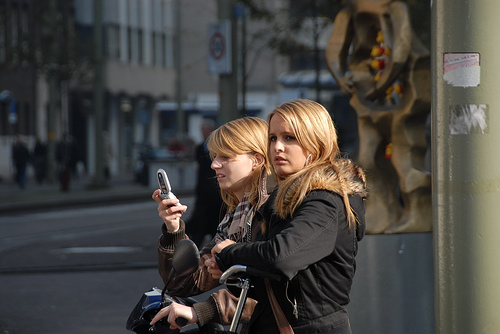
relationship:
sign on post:
[205, 17, 241, 76] [213, 0, 246, 130]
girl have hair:
[152, 99, 367, 333] [205, 100, 362, 220]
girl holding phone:
[152, 99, 367, 333] [150, 166, 177, 200]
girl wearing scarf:
[152, 99, 367, 333] [212, 185, 257, 242]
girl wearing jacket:
[163, 99, 377, 327] [244, 166, 380, 322]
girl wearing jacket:
[152, 99, 367, 333] [238, 163, 369, 323]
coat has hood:
[221, 157, 370, 333] [310, 160, 374, 241]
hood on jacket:
[320, 170, 380, 238] [253, 170, 387, 321]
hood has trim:
[320, 170, 380, 238] [271, 161, 365, 198]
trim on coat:
[275, 159, 371, 198] [221, 157, 370, 333]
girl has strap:
[152, 99, 367, 333] [252, 196, 302, 320]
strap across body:
[252, 196, 302, 320] [246, 170, 360, 316]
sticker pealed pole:
[442, 51, 488, 136] [433, 0, 500, 334]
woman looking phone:
[140, 117, 267, 299] [150, 158, 181, 226]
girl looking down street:
[152, 99, 367, 333] [21, 192, 462, 322]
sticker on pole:
[428, 46, 488, 166] [419, 13, 484, 300]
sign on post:
[205, 19, 232, 76] [206, 13, 246, 224]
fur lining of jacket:
[271, 155, 371, 208] [238, 163, 369, 323]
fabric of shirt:
[208, 184, 262, 253] [206, 177, 276, 248]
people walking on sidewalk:
[9, 133, 95, 203] [5, 178, 187, 219]